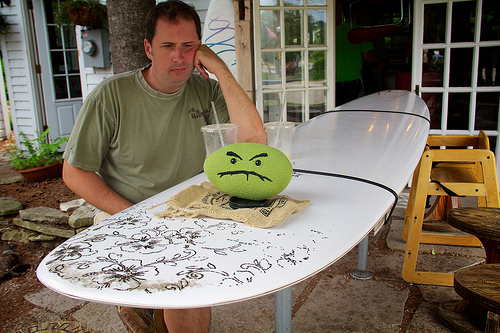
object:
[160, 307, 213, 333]
leg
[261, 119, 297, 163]
cup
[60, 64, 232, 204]
shirt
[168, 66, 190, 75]
mouth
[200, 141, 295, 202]
green oval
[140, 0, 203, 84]
head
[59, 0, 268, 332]
adult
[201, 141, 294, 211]
nut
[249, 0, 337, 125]
door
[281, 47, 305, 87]
glass panels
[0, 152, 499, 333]
porch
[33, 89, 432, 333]
table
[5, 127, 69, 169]
plant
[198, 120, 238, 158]
cup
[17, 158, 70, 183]
planter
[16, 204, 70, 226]
stones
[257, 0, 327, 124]
reflection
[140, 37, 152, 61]
ear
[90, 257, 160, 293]
flower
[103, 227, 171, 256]
print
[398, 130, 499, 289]
chair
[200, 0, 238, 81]
surfboard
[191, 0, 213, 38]
wall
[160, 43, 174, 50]
eyes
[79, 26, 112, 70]
meter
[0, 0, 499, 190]
house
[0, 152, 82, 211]
doorway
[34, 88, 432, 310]
surfboard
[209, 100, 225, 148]
drinking straw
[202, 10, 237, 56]
design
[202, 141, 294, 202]
face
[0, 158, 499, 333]
ground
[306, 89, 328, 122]
window